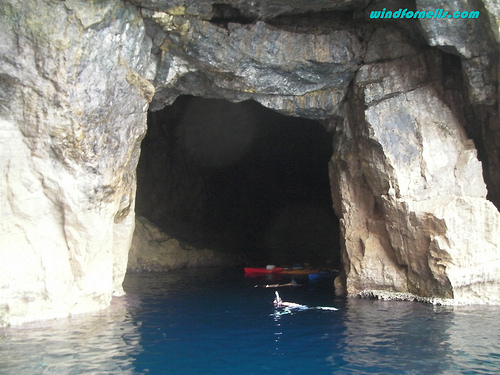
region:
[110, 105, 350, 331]
this is a cave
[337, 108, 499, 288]
this is a stone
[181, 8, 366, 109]
this is a stone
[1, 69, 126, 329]
this is a stone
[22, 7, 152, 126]
this is a stone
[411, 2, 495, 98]
this is a stone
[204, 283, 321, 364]
the water is calm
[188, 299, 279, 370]
the water is calm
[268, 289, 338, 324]
person snorkeling in blue water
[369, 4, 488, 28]
name of photography studio that owns this image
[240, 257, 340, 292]
kayaks parked inside cave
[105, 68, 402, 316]
mouth of an ocean cove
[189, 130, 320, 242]
dark interior deeper into the cove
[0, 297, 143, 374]
rock face reflecting in the water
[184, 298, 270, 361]
deeply blue colored water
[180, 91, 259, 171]
circle of light caused by the sun when taking a photo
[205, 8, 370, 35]
horizontal crevice in rock above the mouth of the cove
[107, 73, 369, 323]
Large opening of cave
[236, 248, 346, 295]
Three canoes in the water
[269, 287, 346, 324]
Someone snorkeling into the cave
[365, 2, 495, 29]
Blue lettering in the corner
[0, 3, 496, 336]
Blak and white rock cave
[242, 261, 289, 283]
Black and red canoe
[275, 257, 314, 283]
Orange canoe in the cave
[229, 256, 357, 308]
Three canoes next to each other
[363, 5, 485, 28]
web adress in teal print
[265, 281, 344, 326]
object in water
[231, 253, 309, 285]
red object in water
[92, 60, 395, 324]
open to underwater cave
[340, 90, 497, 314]
stone wall of cave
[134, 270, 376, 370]
dark shadow on surface of water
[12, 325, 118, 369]
dark line ripples in water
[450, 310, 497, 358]
white light reflected on water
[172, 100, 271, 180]
round light reflected into wall of cave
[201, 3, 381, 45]
dark stain at top of cave opening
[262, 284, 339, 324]
person swimming in the blue water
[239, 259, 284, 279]
small red kayak in the blue water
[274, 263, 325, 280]
small orange kayak in the blue water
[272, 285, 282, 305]
white snorkel on the man's face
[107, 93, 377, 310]
opening to a small cave in the water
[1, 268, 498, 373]
the water is blue and deep looking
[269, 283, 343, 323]
person wearing snorkel gear in the water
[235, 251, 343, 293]
some kayaks parked in the cave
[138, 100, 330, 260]
wall of the small cave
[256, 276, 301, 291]
oar lying in the blue water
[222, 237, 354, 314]
a kayak in the water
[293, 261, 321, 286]
a kayak in the water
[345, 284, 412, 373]
a body of blue water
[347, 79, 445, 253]
a large rock cave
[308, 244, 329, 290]
three kayaks in the water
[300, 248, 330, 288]
a kayak in the cave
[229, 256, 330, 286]
red boat under cave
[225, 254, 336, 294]
red boat under cave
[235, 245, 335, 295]
red boat under cave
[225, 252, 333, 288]
red boat under cave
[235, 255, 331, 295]
red boat under cave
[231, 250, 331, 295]
red boat under cave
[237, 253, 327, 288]
red boat under cave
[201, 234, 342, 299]
boat in the cave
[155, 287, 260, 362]
blue water in cave